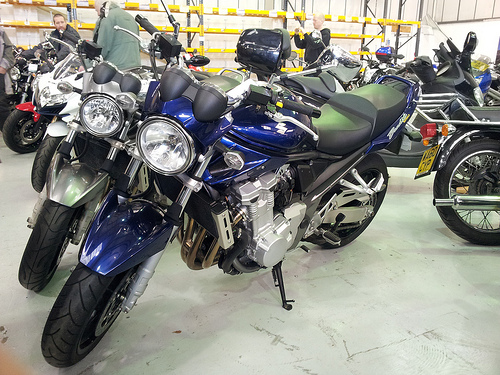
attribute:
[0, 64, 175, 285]
motorcycle — sitting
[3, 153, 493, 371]
floor — flat, light gray, scratched, marked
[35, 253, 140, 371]
wheel — blue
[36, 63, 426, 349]
cycle — black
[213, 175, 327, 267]
engine — silver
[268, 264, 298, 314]
kickstand — black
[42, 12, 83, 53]
man — seated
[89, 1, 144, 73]
man — standing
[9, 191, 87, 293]
tire — black, rubber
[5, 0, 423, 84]
railing — yellow, white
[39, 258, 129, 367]
tire — black, rubber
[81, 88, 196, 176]
unlit headlights — round, shiny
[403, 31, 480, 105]
motorcycle — sitting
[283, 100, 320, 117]
handle — black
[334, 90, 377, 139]
divider — low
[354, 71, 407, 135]
seating — green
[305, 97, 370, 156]
seating — green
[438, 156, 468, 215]
tire — rubber, black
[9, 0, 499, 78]
wall — back